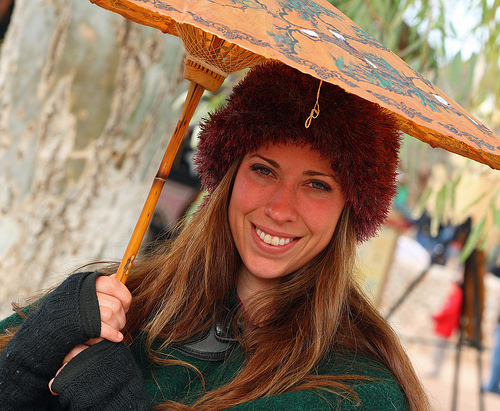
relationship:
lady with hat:
[7, 72, 434, 409] [189, 59, 398, 238]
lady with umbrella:
[7, 72, 434, 409] [6, 0, 497, 278]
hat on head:
[189, 59, 398, 238] [209, 141, 339, 278]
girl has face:
[7, 72, 434, 409] [209, 141, 339, 278]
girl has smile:
[7, 72, 434, 409] [248, 218, 314, 254]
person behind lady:
[429, 281, 466, 378] [7, 72, 434, 409]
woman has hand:
[7, 72, 434, 409] [73, 272, 133, 341]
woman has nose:
[7, 72, 434, 409] [265, 176, 309, 223]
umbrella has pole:
[6, 0, 497, 278] [102, 81, 211, 286]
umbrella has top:
[6, 0, 497, 278] [104, 3, 499, 166]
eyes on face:
[243, 164, 335, 199] [209, 141, 339, 278]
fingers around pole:
[93, 277, 137, 341] [102, 81, 211, 286]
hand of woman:
[73, 272, 133, 341] [7, 72, 434, 409]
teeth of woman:
[255, 225, 293, 247] [7, 72, 434, 409]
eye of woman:
[247, 163, 280, 185] [7, 72, 434, 409]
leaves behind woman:
[337, 2, 499, 137] [7, 72, 434, 409]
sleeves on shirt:
[7, 273, 158, 411] [3, 261, 411, 409]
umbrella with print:
[6, 0, 497, 278] [104, 3, 499, 166]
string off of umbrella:
[293, 76, 329, 126] [6, 0, 497, 278]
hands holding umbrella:
[7, 273, 158, 411] [6, 0, 497, 278]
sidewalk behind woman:
[369, 252, 498, 409] [7, 72, 434, 409]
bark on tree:
[6, 2, 190, 279] [5, 6, 203, 326]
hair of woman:
[11, 153, 431, 409] [7, 72, 434, 409]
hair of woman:
[7, 72, 434, 409] [7, 72, 434, 409]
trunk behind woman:
[6, 2, 190, 279] [7, 72, 434, 409]